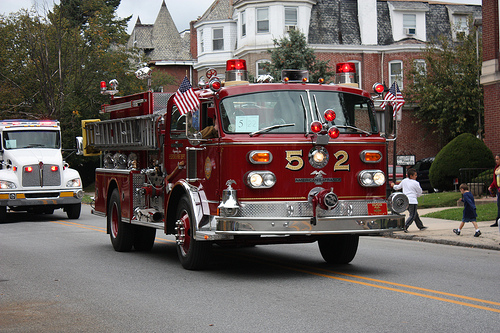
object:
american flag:
[172, 75, 201, 116]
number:
[285, 149, 305, 172]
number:
[333, 150, 350, 173]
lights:
[225, 59, 248, 82]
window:
[388, 60, 403, 91]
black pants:
[404, 204, 423, 230]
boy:
[453, 183, 482, 237]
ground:
[0, 205, 500, 333]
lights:
[243, 171, 277, 189]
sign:
[235, 115, 259, 132]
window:
[219, 89, 379, 134]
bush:
[427, 128, 496, 195]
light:
[249, 150, 274, 165]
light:
[360, 150, 384, 163]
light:
[328, 126, 339, 139]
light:
[311, 121, 323, 133]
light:
[324, 109, 336, 121]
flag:
[379, 81, 405, 118]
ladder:
[76, 113, 162, 156]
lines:
[50, 220, 499, 313]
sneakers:
[474, 230, 482, 237]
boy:
[391, 168, 428, 233]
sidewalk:
[395, 206, 499, 252]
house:
[126, 0, 500, 188]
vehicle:
[0, 119, 84, 220]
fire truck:
[75, 59, 410, 270]